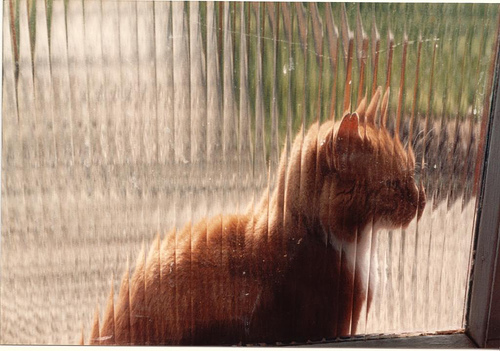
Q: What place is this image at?
A: It is at the yard.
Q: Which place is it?
A: It is a yard.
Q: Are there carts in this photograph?
A: No, there are no carts.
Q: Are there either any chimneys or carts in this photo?
A: No, there are no carts or chimneys.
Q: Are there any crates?
A: No, there are no crates.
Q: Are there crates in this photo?
A: No, there are no crates.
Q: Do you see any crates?
A: No, there are no crates.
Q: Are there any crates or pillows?
A: No, there are no crates or pillows.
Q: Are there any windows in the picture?
A: Yes, there is a window.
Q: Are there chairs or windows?
A: Yes, there is a window.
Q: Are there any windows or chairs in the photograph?
A: Yes, there is a window.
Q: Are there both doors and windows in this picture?
A: Yes, there are both a window and a door.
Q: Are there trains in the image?
A: No, there are no trains.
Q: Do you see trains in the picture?
A: No, there are no trains.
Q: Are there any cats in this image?
A: Yes, there is a cat.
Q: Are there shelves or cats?
A: Yes, there is a cat.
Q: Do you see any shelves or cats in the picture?
A: Yes, there is a cat.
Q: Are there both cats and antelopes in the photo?
A: No, there is a cat but no antelopes.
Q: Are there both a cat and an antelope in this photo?
A: No, there is a cat but no antelopes.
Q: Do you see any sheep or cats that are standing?
A: Yes, the cat is standing.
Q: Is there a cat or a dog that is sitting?
A: Yes, the cat is sitting.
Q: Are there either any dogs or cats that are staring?
A: Yes, the cat is staring.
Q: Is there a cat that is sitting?
A: Yes, there is a cat that is sitting.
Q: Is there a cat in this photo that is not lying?
A: Yes, there is a cat that is sitting.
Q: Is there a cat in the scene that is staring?
A: Yes, there is a cat that is staring.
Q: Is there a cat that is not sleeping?
A: Yes, there is a cat that is staring.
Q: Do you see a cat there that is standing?
A: Yes, there is a cat that is standing.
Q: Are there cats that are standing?
A: Yes, there is a cat that is standing.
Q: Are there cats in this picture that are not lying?
A: Yes, there is a cat that is standing.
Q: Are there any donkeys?
A: No, there are no donkeys.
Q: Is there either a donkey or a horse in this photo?
A: No, there are no donkeys or horses.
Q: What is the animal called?
A: The animal is a cat.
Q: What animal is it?
A: The animal is a cat.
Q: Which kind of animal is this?
A: This is a cat.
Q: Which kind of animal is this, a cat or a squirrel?
A: This is a cat.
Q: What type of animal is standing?
A: The animal is a cat.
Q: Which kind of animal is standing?
A: The animal is a cat.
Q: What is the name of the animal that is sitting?
A: The animal is a cat.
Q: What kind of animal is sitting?
A: The animal is a cat.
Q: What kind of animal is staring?
A: The animal is a cat.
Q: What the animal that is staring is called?
A: The animal is a cat.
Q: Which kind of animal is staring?
A: The animal is a cat.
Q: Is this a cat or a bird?
A: This is a cat.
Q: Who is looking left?
A: The cat is looking left.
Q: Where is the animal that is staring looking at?
A: The cat is looking left.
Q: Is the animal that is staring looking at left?
A: Yes, the cat is looking left.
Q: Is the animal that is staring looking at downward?
A: No, the cat is looking left.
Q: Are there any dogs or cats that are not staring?
A: No, there is a cat but it is staring.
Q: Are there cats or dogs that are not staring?
A: No, there is a cat but it is staring.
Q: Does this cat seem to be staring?
A: Yes, the cat is staring.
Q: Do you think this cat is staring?
A: Yes, the cat is staring.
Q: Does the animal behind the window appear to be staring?
A: Yes, the cat is staring.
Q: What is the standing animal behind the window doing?
A: The cat is staring.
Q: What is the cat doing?
A: The cat is staring.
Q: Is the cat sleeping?
A: No, the cat is staring.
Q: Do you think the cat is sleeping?
A: No, the cat is staring.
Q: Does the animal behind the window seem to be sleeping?
A: No, the cat is staring.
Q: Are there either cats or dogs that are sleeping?
A: No, there is a cat but it is staring.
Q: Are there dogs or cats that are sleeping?
A: No, there is a cat but it is staring.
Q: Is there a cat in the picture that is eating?
A: No, there is a cat but it is staring.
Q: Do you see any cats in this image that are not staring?
A: No, there is a cat but it is staring.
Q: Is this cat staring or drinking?
A: The cat is staring.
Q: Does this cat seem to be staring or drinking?
A: The cat is staring.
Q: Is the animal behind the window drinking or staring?
A: The cat is staring.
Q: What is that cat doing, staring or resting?
A: The cat is staring.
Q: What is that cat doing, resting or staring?
A: The cat is staring.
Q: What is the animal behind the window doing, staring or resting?
A: The cat is staring.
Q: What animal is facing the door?
A: The cat is facing the door.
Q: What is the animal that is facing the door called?
A: The animal is a cat.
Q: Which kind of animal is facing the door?
A: The animal is a cat.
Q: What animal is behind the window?
A: The animal is a cat.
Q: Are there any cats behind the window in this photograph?
A: Yes, there is a cat behind the window.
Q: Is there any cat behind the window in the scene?
A: Yes, there is a cat behind the window.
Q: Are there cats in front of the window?
A: No, the cat is behind the window.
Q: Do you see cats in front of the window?
A: No, the cat is behind the window.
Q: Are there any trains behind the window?
A: No, there is a cat behind the window.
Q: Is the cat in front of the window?
A: No, the cat is behind the window.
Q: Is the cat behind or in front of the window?
A: The cat is behind the window.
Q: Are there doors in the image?
A: Yes, there is a door.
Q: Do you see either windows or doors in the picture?
A: Yes, there is a door.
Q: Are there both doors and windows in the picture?
A: Yes, there are both a door and a window.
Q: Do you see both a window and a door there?
A: Yes, there are both a door and a window.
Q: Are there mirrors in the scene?
A: No, there are no mirrors.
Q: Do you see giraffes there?
A: No, there are no giraffes.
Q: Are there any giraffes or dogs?
A: No, there are no giraffes or dogs.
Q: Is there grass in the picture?
A: Yes, there is grass.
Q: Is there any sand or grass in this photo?
A: Yes, there is grass.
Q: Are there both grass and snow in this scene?
A: No, there is grass but no snow.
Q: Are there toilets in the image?
A: No, there are no toilets.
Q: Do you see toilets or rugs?
A: No, there are no toilets or rugs.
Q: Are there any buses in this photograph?
A: No, there are no buses.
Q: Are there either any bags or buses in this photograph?
A: No, there are no buses or bags.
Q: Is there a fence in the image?
A: No, there are no fences.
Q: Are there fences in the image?
A: No, there are no fences.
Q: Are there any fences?
A: No, there are no fences.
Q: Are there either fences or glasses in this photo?
A: No, there are no fences or glasses.